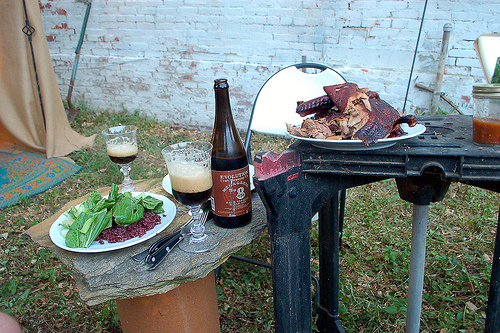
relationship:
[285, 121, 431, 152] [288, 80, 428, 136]
plate with meat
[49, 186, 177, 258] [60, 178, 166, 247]
plate with vegetables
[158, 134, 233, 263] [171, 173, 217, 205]
glass filled beverage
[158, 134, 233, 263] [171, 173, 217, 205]
glass with drink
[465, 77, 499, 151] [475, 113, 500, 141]
jar filled with liquid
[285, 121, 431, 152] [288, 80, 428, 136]
plate of ribs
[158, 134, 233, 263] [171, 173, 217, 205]
glass of beer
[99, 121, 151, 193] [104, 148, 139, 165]
glass of beer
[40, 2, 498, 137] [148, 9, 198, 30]
wall of bricks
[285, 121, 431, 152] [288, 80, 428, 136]
plate of meat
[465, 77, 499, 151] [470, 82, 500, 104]
jar with lid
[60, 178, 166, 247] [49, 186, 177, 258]
vegetables on plate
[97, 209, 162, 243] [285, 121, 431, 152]
beans on plate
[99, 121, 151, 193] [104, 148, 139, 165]
cup of beer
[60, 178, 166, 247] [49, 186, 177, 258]
vegetables in dish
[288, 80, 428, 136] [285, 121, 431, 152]
meat on dish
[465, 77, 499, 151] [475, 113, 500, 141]
jar of sauce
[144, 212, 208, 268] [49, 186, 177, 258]
fork beside dish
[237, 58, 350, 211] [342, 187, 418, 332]
chair on grass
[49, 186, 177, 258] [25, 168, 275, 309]
dish over stone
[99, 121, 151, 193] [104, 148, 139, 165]
glass with beer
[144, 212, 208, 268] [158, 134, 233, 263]
fork next to glass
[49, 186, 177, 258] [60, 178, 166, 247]
plate of greens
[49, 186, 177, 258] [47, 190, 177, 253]
lettuce lying on top of plate